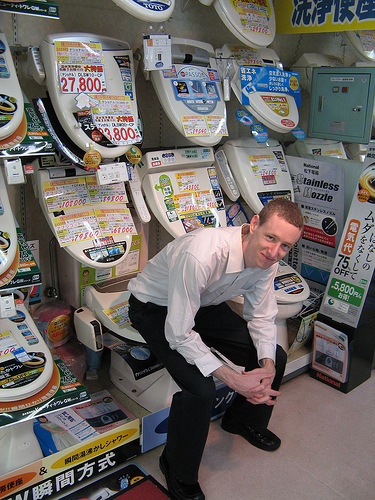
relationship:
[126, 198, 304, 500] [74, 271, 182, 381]
boy on toilet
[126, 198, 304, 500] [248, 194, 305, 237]
boy has hair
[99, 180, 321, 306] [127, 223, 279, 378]
boy has shirt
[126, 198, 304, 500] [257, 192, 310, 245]
boy with hair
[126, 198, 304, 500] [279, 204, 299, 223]
boy with red hair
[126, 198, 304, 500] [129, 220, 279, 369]
boy wearing white shirt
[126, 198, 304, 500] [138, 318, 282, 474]
boy wearing black pants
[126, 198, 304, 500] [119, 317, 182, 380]
boy sitting on toilet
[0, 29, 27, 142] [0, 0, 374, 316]
toilet displayed on wall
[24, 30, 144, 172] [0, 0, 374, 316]
toilet displayed on wall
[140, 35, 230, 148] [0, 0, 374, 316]
toilet displayed on wall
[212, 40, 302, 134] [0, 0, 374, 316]
toilet displayed on wall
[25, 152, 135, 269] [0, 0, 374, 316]
toilet displayed on wall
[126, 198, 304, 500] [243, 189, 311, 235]
boy with hair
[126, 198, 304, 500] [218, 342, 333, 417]
boy sitting with folded hands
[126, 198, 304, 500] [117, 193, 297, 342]
boy a man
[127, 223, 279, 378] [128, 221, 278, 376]
shirt a shirt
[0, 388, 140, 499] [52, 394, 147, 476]
box a box